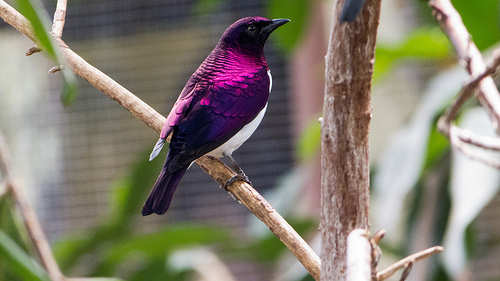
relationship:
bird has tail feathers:
[139, 15, 291, 218] [134, 166, 186, 216]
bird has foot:
[139, 15, 292, 217] [219, 169, 255, 194]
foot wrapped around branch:
[219, 169, 255, 194] [3, 2, 323, 277]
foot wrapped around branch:
[219, 169, 251, 194] [44, 43, 319, 264]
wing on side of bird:
[152, 68, 188, 168] [139, 15, 291, 218]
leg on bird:
[211, 150, 269, 190] [139, 15, 291, 218]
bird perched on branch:
[139, 15, 292, 217] [3, 2, 323, 277]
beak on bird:
[261, 18, 292, 37] [139, 15, 292, 217]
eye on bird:
[249, 24, 256, 31] [139, 15, 292, 217]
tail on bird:
[133, 142, 195, 218] [139, 15, 292, 217]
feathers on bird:
[152, 169, 181, 217] [139, 15, 292, 217]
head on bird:
[226, 11, 294, 48] [139, 15, 292, 217]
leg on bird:
[211, 150, 244, 175] [147, 12, 311, 242]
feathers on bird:
[213, 57, 251, 89] [139, 15, 292, 217]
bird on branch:
[139, 15, 291, 218] [3, 2, 323, 277]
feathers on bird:
[139, 152, 184, 217] [139, 15, 292, 217]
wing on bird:
[199, 69, 255, 119] [139, 15, 292, 217]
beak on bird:
[261, 11, 290, 40] [116, 17, 341, 195]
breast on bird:
[208, 67, 273, 166] [139, 15, 292, 217]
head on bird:
[216, 14, 290, 48] [139, 15, 292, 217]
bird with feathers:
[139, 15, 291, 218] [195, 58, 234, 100]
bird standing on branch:
[139, 15, 292, 217] [44, 43, 319, 264]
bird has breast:
[139, 15, 292, 217] [208, 67, 271, 102]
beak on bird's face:
[261, 18, 292, 37] [229, 15, 276, 59]